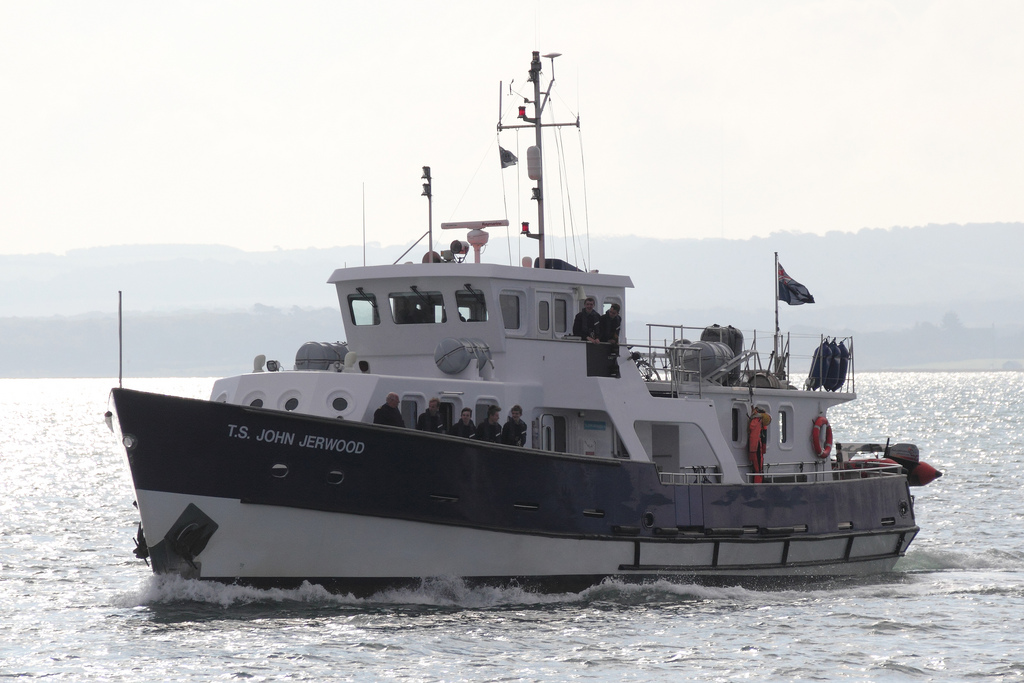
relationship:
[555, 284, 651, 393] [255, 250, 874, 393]
people standing on level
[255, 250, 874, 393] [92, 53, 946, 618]
level of boat